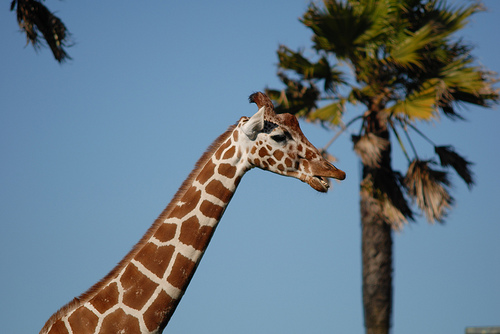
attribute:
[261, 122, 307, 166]
eye — dark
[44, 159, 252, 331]
neck — giraffe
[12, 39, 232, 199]
sky — bright blue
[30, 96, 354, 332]
giraffe's mouth — open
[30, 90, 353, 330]
giraffe — brown , white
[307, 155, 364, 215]
mouth — open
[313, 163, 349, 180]
lip — top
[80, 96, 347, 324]
giraffe — spotted